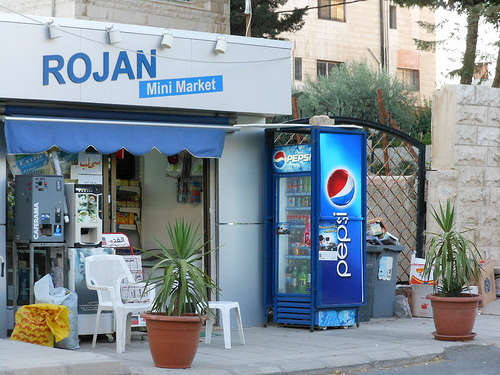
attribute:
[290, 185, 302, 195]
soda — pepsi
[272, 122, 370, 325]
cooler — blue, soda, machine, pepsi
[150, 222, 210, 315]
plant — green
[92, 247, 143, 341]
stool — white, plastic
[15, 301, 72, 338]
bag — yellow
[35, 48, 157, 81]
rojan — maket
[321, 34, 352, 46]
wall — stone, brick, gray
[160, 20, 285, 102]
sign — white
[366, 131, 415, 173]
gate — black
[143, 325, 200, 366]
pot — orange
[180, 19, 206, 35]
roof — white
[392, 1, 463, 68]
building — background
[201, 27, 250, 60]
light — off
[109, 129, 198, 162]
awning — blue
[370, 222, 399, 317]
trash can — full